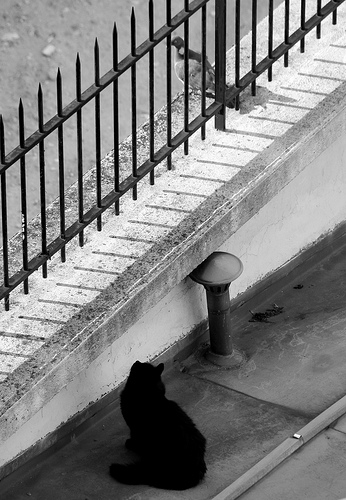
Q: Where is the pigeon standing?
A: On the ledge of a building.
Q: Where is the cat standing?
A: On the roof of the building.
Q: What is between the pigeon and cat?
A: An iron fence.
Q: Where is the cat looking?
A: Up at the pigeon.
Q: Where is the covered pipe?
A: On the roof beside the cat.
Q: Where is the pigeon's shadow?
A: Behind the pigeon.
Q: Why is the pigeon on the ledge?
A: To rest.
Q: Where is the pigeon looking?
A: To the left.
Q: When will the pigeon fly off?
A: When the cat gets too close.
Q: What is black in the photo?
A: Bars.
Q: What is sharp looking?
A: Bars.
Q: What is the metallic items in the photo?
A: Bars.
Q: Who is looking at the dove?
A: Cat.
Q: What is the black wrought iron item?
A: Fence.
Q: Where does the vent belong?
A: Roof top.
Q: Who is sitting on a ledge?
A: Pigeon.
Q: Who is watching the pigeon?
A: Cat.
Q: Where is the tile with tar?
A: Roof.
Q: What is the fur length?
A: Long.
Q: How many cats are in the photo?
A: One.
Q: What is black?
A: A cat.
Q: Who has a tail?
A: Cat.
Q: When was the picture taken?
A: Daytime.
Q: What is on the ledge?
A: A bird.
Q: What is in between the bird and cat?
A: Railings.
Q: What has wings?
A: The bird.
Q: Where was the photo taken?
A: On a roof.